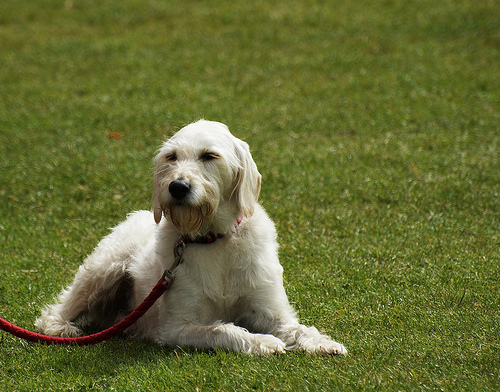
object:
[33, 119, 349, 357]
dog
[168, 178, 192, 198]
nose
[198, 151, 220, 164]
eye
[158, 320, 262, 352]
front leg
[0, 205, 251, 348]
leash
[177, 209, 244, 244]
collar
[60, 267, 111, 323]
back leg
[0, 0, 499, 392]
grass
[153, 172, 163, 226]
right ear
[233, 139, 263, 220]
left ear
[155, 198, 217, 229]
mouth hair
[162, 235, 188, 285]
buckle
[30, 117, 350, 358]
fur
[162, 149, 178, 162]
eye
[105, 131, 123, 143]
leaf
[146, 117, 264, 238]
head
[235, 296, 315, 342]
leg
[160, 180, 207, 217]
mouth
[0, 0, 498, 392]
field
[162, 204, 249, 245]
neck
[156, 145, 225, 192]
face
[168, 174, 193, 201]
snout